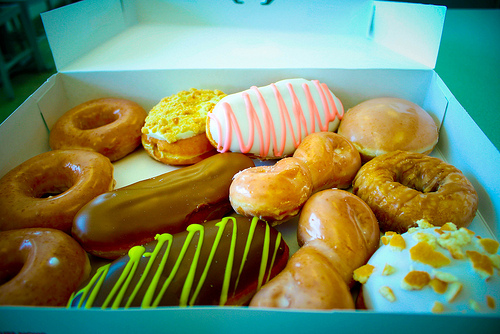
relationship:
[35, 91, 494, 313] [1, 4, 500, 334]
donuts inside of box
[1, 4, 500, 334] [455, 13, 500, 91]
box on top of table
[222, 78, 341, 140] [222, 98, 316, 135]
donut has glaze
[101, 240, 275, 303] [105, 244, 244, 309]
donut has glaze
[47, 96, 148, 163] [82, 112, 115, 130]
donuts has hole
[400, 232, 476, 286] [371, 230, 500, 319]
topping sprinkled on donut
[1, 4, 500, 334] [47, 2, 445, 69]
box has lid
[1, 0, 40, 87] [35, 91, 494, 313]
cart behind donuts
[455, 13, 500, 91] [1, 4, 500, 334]
table under box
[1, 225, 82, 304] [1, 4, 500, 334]
donut inside of box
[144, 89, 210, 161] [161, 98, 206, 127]
donut has topping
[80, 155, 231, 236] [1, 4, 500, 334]
donut inside of box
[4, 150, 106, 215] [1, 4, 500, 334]
donut inside of box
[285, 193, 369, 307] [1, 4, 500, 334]
donut inside of box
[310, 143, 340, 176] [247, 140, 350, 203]
sugar glaze on top of donut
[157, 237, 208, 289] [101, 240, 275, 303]
stripes are on top of chocolate eclair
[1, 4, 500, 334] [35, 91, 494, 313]
box holding donuts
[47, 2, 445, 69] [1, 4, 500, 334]
lid of box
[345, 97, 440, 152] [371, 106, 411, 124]
donut has sugar glaze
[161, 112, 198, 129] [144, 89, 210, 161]
nuts are on top of donut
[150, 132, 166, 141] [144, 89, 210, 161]
glaze on top of donut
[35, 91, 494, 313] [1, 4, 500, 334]
donuts are inside of box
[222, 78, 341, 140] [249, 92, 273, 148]
donut with stripes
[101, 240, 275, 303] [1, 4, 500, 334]
chocolate eclair inside of box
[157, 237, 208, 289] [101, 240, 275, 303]
stripes on top of donut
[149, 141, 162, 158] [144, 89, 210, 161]
hole on side of donut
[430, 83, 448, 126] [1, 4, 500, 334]
cardboard flap on side of box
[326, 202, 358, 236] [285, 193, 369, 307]
glaze on top of donut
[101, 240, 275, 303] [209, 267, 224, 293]
donut covered in chocolate